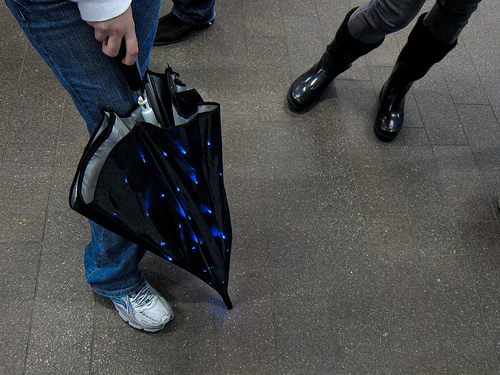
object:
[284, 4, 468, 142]
boots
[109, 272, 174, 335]
shoe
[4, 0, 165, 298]
jeans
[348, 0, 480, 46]
pants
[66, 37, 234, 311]
umbrella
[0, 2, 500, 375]
floor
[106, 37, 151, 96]
handle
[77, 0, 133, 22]
shirt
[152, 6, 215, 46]
shoe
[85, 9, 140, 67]
hand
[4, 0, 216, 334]
person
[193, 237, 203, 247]
light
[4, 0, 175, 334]
woman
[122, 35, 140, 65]
finger